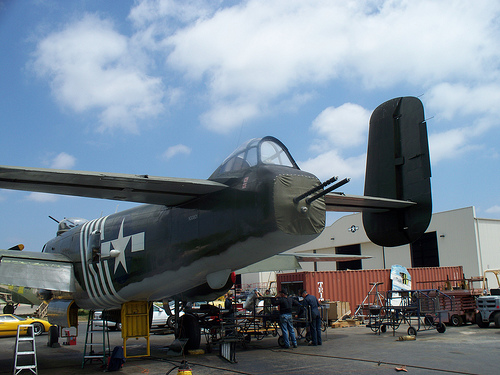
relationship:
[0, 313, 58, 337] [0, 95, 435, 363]
car parked near airplane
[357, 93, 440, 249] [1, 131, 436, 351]
mirror on airplane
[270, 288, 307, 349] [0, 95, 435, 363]
man standing under airplane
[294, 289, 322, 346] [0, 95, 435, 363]
man standing under airplane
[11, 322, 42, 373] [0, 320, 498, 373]
ladder on road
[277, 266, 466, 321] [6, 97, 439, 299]
container by plane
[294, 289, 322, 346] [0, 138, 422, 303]
man standing under airplane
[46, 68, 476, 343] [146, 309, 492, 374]
airplane on runway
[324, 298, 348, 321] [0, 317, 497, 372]
boxes on ground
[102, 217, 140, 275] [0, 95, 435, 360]
star on airplane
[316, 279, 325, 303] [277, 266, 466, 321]
letters on container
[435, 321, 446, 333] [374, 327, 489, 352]
black wheels on scaffolding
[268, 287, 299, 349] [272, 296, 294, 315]
man wearing shirt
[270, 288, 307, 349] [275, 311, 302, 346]
man wearing blue jeans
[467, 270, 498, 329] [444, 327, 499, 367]
forklift parked on road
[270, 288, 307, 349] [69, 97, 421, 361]
man working on airplane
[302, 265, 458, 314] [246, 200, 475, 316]
dumpster along building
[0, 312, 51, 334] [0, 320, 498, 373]
car parked on road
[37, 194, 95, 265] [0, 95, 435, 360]
propeller on airplane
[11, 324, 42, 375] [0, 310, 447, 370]
ladder on runway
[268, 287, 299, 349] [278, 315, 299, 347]
man in jeans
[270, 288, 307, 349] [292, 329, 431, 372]
man on runway